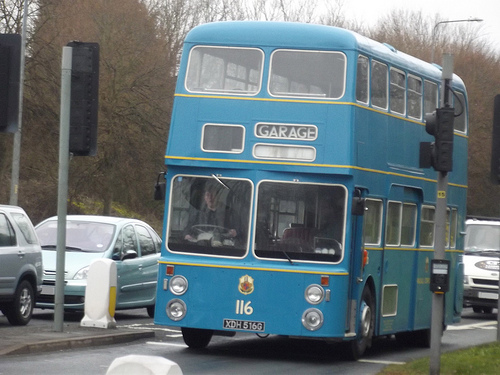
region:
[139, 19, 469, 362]
Blue double-decker bus.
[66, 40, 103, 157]
The black back of a stop light.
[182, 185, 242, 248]
Bus driver in a black coat.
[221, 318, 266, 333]
The bus' license plate.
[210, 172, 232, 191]
The bus' driver-side windshield wiper.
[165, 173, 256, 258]
Bus' front driver-side windshield.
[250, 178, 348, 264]
Bus' front passenger-side windshield.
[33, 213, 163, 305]
A bluish car next to the bus.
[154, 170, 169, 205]
The bus' driver-side rear view mirror.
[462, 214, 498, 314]
A white truck behind the bus.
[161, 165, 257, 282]
Window of a bus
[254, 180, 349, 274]
Window of a bus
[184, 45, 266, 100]
Window of a bus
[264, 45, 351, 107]
Window of a bus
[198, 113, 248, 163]
Window of a bus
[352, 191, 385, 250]
Window of a bus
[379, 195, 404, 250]
Window of a bus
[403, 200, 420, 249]
Window of a bus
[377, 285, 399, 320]
Window of a bus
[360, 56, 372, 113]
Window of a bus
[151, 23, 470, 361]
Double-decker bus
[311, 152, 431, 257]
Stairs to get to the bus's second deck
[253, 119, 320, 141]
Bus's destination (parking garage)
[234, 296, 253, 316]
The bus's number in the transit system (116)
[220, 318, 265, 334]
Bus's license plate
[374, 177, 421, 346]
Door for boarding the bus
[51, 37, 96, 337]
Traffic signal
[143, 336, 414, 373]
Stop line for traffic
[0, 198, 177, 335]
Two neighboring cars (one is partially off camera)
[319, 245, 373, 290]
Bus's left turn signal lights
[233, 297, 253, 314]
116 on a bus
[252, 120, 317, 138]
GARAGE on a bus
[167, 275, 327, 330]
Headlights on a blue bus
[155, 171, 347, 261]
Windshield on a bus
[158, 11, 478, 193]
Second level on a blue bus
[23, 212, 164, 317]
Blue car on the street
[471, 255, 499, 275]
Black symbol on a car's hood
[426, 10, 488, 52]
Light on a post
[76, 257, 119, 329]
White divider on a sidewalk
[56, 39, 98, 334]
Black sign on a metal post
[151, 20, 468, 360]
Blue and white double decker bus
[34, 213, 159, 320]
Sedan waits in traffic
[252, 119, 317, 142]
Bus destination indicator sign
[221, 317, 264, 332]
Black and white front license plate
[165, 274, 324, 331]
Circular headlights on bus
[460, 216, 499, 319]
White SUV behind bus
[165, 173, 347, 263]
Front windshield of bus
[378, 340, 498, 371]
Small patch of grass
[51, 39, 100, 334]
Traffic lights on electric pole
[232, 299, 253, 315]
Bus identification number